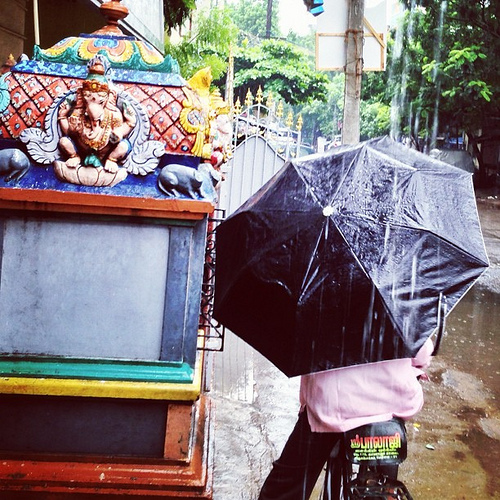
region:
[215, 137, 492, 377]
the umbrella is black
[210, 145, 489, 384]
the umbrella is wet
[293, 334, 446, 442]
woman's jacket is pink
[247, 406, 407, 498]
woman's pants are black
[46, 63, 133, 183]
monkey on the statue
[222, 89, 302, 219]
metal gate behind the statue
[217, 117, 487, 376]
umbrella blocking woman's face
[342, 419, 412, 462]
orange and yellow letters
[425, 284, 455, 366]
strap hanging from umbrella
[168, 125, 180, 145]
blue dot on wall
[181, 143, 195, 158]
blue dot on wall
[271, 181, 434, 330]
a black umbrella outside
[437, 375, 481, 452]
brown road on ground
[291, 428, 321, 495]
black pants on person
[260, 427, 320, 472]
left leg on person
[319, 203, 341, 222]
White tip of open umbrella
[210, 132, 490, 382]
Open large black umbrella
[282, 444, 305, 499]
Part of bike rider's leg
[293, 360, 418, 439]
Part of pink shirt worn by rider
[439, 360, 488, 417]
Part of rock near rider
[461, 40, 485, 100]
Part of green trees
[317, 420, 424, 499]
Part of bike ridden by person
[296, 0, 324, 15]
Part of hanging traffic signal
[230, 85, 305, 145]
Part of decorative spikes on fence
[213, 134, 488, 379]
An open dark umbrella wet from rain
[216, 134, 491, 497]
Person on a bike under an umbrella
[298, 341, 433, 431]
Person's pink top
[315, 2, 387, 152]
Wooden post holding a white sign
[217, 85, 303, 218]
Grey metal fence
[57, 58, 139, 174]
Statue of Ganesh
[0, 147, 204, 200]
Animal bodies carved as reliefs on top of a box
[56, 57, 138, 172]
Decoration with a person's body and an elephant's head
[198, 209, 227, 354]
Decorative black metal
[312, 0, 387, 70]
Back of a white sign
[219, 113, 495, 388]
open black umbrella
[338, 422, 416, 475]
label on back of bicycle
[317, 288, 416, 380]
rain falling in sky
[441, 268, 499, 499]
water in center of street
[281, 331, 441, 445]
long sleeve pink shirt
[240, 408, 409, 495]
pair of black pants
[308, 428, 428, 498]
back of bicycle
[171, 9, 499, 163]
tall green trees